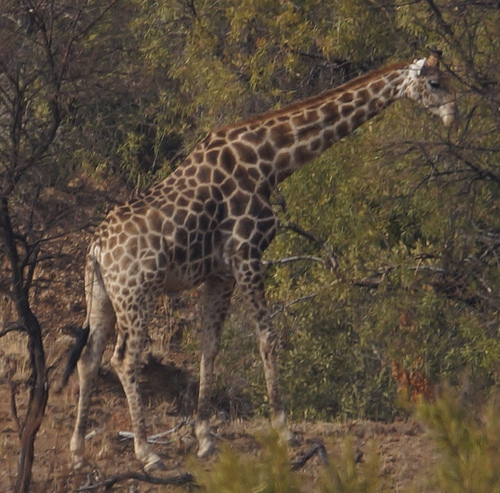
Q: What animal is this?
A: Giraffe.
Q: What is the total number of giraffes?
A: 1.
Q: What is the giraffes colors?
A: Brown and white.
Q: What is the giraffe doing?
A: Standing.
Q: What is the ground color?
A: Brown.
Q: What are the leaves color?
A: Green.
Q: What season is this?
A: Summer.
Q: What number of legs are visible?
A: 4.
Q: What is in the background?
A: Trees.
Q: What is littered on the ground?
A: Sticks.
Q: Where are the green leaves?
A: Trees.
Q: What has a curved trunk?
A: Tree on left.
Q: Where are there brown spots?
A: Giraffe body.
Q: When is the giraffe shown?
A: During the light of day.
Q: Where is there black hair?
A: Giraffe tail.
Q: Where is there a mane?
A: Giraffe neck.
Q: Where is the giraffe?
A: Natural habitat.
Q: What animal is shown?
A: A giraffe.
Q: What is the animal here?
A: Giraffe.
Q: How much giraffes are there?
A: 1.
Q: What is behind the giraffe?
A: Trees.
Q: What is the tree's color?
A: Green.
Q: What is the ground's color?
A: Brown.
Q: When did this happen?
A: During the day time.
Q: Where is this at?
A: Forest.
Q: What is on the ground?
A: Branches.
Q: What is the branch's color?
A: Brown.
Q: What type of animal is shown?
A: Giraffe.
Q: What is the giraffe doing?
A: Walking.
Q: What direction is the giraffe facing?
A: Right.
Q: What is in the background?
A: Trees.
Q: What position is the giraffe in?
A: Standing.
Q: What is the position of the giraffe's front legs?
A: Spread apart.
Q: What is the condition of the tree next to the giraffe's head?
A: Bare.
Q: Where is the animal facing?
A: To the right.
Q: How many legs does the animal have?
A: Four.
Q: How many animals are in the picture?
A: One.